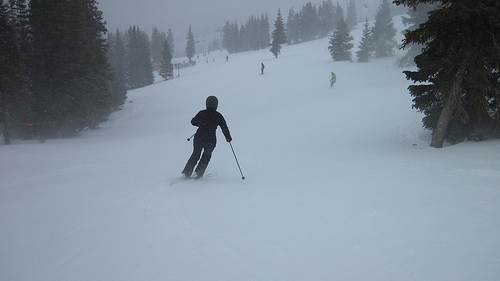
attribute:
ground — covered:
[57, 164, 373, 278]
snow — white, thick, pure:
[139, 65, 400, 227]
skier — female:
[190, 83, 248, 192]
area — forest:
[9, 21, 161, 89]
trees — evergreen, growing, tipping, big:
[38, 31, 213, 105]